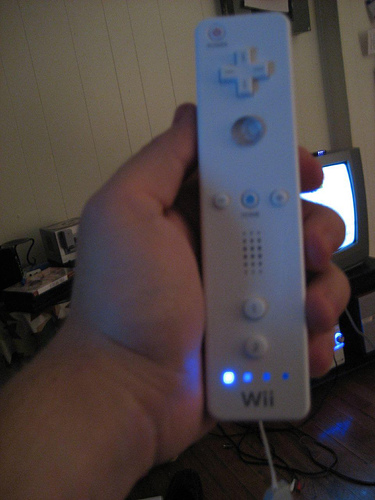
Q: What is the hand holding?
A: Wii remote control.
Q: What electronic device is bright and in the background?
A: Tv.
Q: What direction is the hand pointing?
A: Left.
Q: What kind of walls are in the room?
A: White panels.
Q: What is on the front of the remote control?
A: Buttons.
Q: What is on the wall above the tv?
A: Picture.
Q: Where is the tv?
A: Table.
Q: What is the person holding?
A: A Wii remote.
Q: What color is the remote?
A: White.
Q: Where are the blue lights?
A: At the bottom of the remote.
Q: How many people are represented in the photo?
A: One.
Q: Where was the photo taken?
A: In a living room.